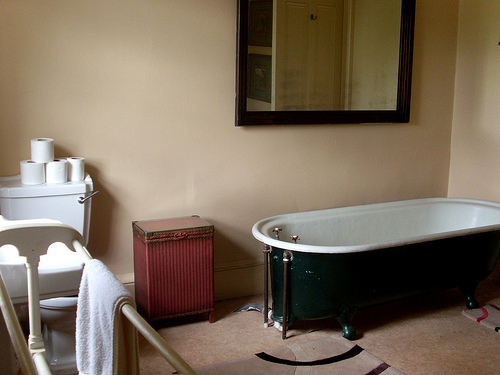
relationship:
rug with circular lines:
[176, 329, 404, 372] [257, 342, 363, 367]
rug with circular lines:
[176, 329, 404, 372] [476, 302, 488, 326]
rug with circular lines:
[176, 329, 404, 372] [486, 302, 499, 335]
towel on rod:
[73, 262, 133, 373] [70, 222, 192, 368]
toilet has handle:
[2, 172, 98, 368] [76, 189, 101, 204]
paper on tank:
[18, 125, 90, 185] [1, 178, 94, 303]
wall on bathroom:
[0, 0, 499, 283] [2, 4, 496, 374]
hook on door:
[308, 7, 318, 22] [269, 0, 351, 114]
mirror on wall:
[0, 1, 472, 166] [30, 18, 250, 130]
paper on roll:
[18, 125, 90, 185] [67, 158, 90, 182]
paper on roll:
[18, 125, 90, 185] [43, 159, 69, 185]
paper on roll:
[18, 125, 90, 185] [29, 137, 58, 160]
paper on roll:
[18, 125, 90, 185] [20, 160, 44, 185]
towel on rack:
[73, 262, 133, 373] [67, 240, 197, 371]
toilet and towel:
[2, 172, 98, 368] [73, 262, 133, 373]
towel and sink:
[73, 262, 133, 373] [1, 216, 93, 305]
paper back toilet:
[18, 125, 90, 185] [2, 172, 98, 368]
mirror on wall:
[233, 1, 419, 129] [0, 1, 498, 301]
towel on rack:
[73, 262, 133, 373] [76, 232, 203, 372]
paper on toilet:
[18, 125, 90, 185] [2, 172, 98, 368]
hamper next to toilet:
[130, 215, 226, 327] [2, 172, 98, 368]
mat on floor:
[223, 323, 397, 373] [194, 324, 460, 373]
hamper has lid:
[122, 212, 223, 341] [129, 217, 221, 244]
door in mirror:
[272, 2, 344, 109] [233, 1, 419, 129]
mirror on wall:
[233, 1, 419, 129] [0, 0, 457, 290]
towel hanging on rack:
[73, 262, 133, 373] [0, 222, 196, 374]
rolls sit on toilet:
[15, 137, 87, 184] [0, 153, 114, 374]